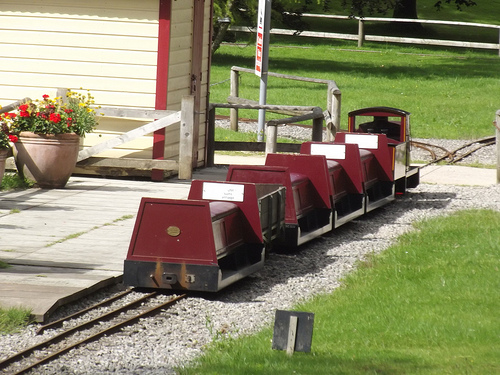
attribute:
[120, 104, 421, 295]
passenger train — small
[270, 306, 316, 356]
sign — small, metal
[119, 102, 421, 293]
train — small , black electric , red , mini, maroon, empty, small electric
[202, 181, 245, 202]
sign — white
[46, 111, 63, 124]
flower — red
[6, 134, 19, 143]
flower — red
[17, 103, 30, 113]
flower — red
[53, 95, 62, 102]
flower — yellow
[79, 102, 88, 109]
flower — yellow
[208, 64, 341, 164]
fence — wooden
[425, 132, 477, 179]
track — Rusty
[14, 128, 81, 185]
pot — planter 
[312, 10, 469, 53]
fence — wooden 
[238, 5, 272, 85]
sign — metal 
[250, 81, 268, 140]
post — wooden 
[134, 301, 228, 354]
path — pebble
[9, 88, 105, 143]
flowers — red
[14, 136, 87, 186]
pot — planter 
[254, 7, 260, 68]
writing — red, black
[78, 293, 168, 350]
trail — metal train 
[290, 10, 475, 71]
fence — small wooden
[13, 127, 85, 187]
pot — planter 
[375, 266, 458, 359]
grass — green 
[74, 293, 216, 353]
ballast — track 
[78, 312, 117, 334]
ties — railroad 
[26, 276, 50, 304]
concrete — prestressed 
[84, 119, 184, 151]
stick — wooden 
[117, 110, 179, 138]
wood — planks  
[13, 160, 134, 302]
platform — station 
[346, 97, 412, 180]
cart — head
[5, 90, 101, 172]
flowers — red , yellow 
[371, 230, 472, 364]
grass — patch , green 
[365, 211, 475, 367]
grass — green , patch 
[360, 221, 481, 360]
grass — green , patch 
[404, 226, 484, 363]
grass — green , patch 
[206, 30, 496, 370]
grass — green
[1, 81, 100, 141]
flowers — red and yellow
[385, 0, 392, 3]
area — grassy 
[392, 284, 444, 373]
grass — green 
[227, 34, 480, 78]
tree — big , shadow 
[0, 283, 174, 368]
tracks —  metal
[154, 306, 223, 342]
rocks — grey 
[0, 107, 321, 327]
deck — wood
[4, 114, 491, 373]
gravel — Grey 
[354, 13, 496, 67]
fence — wooden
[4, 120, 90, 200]
pot — brown 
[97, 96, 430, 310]
toy train — red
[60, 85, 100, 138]
flowers — yellow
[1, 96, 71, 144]
flowers — red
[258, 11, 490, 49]
fence — wood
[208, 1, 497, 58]
fence — wooden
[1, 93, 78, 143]
flowers — red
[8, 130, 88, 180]
pot — terracotta